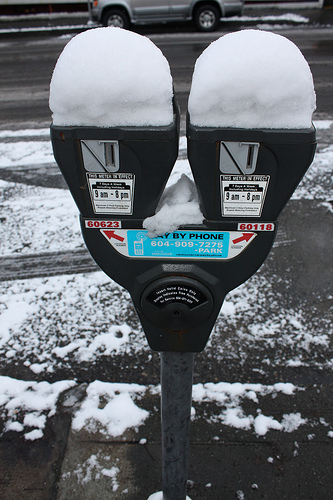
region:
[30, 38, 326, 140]
The parking meter has snow on top.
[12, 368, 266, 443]
Snow is on the ground.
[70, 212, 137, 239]
The meter has the number 60623 written on it.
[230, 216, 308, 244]
The meter has the number 60118 written on it.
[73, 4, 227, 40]
a car is parked on the street.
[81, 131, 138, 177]
The coin slot of the parking meter.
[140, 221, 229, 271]
The parking meter has a phone number written on it.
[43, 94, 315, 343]
Two parking meters on one pole.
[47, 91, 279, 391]
The parking meter is on the sidewalk.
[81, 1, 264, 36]
The car is silver.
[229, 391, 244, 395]
section of white snow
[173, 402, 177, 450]
section of a pole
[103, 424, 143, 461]
edge of a road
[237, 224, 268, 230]
number on a sticker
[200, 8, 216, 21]
back wheel of a car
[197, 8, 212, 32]
wheel cap of a car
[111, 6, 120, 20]
front wheel of a car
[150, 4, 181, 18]
body of a car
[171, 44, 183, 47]
section of a road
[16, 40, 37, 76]
part of a road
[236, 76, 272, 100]
part of some snow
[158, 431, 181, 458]
part of a post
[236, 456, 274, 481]
part of the floor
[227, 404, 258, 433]
part of some snow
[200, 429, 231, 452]
part of a line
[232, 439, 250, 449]
part of a line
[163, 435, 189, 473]
part of a post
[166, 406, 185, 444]
edge of a post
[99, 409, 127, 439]
part of a snow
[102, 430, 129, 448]
edge of a snow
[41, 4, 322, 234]
2 Parking Meters on one Pole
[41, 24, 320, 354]
Snow on Parking Meters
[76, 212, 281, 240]
Parking Meters Identity Numbers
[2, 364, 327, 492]
Snow on Sidewalk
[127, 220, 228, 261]
Pay By Phone to Park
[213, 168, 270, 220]
Hours Parking Payment is required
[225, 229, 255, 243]
Red Arrow Pointing Up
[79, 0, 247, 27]
Truck Parked on Street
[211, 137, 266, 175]
Parking Meter Coin Slot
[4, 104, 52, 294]
Tire Tracks in Snow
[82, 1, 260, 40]
the car in the background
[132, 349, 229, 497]
the pole of the meter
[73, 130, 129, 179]
the coin slot on the meter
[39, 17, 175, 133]
the snow on the meter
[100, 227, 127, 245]
the red arrow on the meter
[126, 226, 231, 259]
the blue sticker on the meter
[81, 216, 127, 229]
the number "60623" on the meter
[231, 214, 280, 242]
the number "60118" on the meter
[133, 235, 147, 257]
the image of the cell phone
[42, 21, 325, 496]
a double parking meter